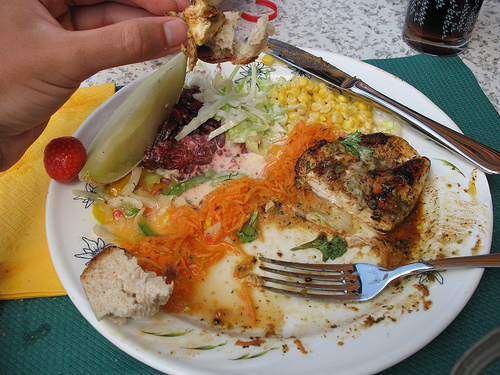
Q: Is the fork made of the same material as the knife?
A: Yes, both the fork and the knife are made of metal.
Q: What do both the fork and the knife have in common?
A: The material, both the fork and the knife are metallic.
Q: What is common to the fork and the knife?
A: The material, both the fork and the knife are metallic.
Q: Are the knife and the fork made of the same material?
A: Yes, both the knife and the fork are made of metal.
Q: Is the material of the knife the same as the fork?
A: Yes, both the knife and the fork are made of metal.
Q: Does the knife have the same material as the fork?
A: Yes, both the knife and the fork are made of metal.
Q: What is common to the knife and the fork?
A: The material, both the knife and the fork are metallic.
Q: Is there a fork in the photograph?
A: Yes, there is a fork.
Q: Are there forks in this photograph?
A: Yes, there is a fork.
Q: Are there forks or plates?
A: Yes, there is a fork.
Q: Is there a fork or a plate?
A: Yes, there is a fork.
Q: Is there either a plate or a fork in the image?
A: Yes, there is a fork.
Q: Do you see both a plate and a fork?
A: Yes, there are both a fork and a plate.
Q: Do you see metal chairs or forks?
A: Yes, there is a metal fork.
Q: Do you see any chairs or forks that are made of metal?
A: Yes, the fork is made of metal.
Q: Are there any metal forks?
A: Yes, there is a metal fork.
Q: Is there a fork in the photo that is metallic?
A: Yes, there is a fork that is metallic.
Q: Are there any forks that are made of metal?
A: Yes, there is a fork that is made of metal.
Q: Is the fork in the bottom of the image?
A: Yes, the fork is in the bottom of the image.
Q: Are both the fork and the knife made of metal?
A: Yes, both the fork and the knife are made of metal.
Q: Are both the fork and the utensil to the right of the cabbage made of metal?
A: Yes, both the fork and the knife are made of metal.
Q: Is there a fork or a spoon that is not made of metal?
A: No, there is a fork but it is made of metal.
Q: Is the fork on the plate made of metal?
A: Yes, the fork is made of metal.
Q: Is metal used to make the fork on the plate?
A: Yes, the fork is made of metal.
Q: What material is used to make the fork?
A: The fork is made of metal.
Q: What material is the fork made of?
A: The fork is made of metal.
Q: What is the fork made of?
A: The fork is made of metal.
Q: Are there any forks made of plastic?
A: No, there is a fork but it is made of metal.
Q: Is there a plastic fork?
A: No, there is a fork but it is made of metal.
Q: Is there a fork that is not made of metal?
A: No, there is a fork but it is made of metal.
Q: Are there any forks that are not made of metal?
A: No, there is a fork but it is made of metal.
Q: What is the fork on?
A: The fork is on the plate.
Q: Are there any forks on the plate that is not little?
A: Yes, there is a fork on the plate.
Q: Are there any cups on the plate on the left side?
A: No, there is a fork on the plate.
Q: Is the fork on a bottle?
A: No, the fork is on the plate.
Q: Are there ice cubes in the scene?
A: No, there are no ice cubes.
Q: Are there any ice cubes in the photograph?
A: No, there are no ice cubes.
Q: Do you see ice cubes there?
A: No, there are no ice cubes.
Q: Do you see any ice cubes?
A: No, there are no ice cubes.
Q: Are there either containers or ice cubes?
A: No, there are no ice cubes or containers.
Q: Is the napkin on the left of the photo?
A: Yes, the napkin is on the left of the image.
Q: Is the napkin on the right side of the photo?
A: No, the napkin is on the left of the image.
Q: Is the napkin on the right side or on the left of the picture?
A: The napkin is on the left of the image.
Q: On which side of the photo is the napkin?
A: The napkin is on the left of the image.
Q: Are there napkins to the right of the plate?
A: No, the napkin is to the left of the plate.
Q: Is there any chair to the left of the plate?
A: No, there is a napkin to the left of the plate.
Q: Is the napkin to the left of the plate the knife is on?
A: Yes, the napkin is to the left of the plate.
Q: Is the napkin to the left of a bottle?
A: No, the napkin is to the left of the plate.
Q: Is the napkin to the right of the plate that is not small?
A: No, the napkin is to the left of the plate.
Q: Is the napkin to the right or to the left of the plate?
A: The napkin is to the left of the plate.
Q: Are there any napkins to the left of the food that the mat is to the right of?
A: Yes, there is a napkin to the left of the food.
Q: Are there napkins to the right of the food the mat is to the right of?
A: No, the napkin is to the left of the food.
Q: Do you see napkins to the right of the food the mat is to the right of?
A: No, the napkin is to the left of the food.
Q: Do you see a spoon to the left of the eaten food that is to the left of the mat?
A: No, there is a napkin to the left of the food.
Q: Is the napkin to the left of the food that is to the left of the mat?
A: Yes, the napkin is to the left of the food.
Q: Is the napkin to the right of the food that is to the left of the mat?
A: No, the napkin is to the left of the food.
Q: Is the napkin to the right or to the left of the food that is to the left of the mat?
A: The napkin is to the left of the food.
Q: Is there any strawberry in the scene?
A: Yes, there is a strawberry.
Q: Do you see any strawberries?
A: Yes, there is a strawberry.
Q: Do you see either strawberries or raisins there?
A: Yes, there is a strawberry.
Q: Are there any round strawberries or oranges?
A: Yes, there is a round strawberry.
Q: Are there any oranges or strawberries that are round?
A: Yes, the strawberry is round.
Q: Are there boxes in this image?
A: No, there are no boxes.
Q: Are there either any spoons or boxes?
A: No, there are no boxes or spoons.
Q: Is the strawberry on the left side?
A: Yes, the strawberry is on the left of the image.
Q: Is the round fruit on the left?
A: Yes, the strawberry is on the left of the image.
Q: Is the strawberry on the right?
A: No, the strawberry is on the left of the image.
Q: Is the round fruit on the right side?
A: No, the strawberry is on the left of the image.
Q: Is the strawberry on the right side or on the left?
A: The strawberry is on the left of the image.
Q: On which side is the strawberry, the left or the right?
A: The strawberry is on the left of the image.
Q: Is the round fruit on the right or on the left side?
A: The strawberry is on the left of the image.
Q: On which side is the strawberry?
A: The strawberry is on the left of the image.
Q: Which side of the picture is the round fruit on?
A: The strawberry is on the left of the image.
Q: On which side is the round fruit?
A: The strawberry is on the left of the image.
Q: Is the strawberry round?
A: Yes, the strawberry is round.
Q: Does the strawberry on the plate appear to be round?
A: Yes, the strawberry is round.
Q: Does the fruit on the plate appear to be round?
A: Yes, the strawberry is round.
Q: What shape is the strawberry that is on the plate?
A: The strawberry is round.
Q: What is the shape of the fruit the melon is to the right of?
A: The strawberry is round.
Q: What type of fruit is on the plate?
A: The fruit is a strawberry.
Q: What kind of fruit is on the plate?
A: The fruit is a strawberry.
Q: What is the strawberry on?
A: The strawberry is on the plate.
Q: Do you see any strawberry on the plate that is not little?
A: Yes, there is a strawberry on the plate.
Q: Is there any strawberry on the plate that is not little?
A: Yes, there is a strawberry on the plate.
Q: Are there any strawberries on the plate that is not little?
A: Yes, there is a strawberry on the plate.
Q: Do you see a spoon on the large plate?
A: No, there is a strawberry on the plate.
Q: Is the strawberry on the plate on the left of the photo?
A: Yes, the strawberry is on the plate.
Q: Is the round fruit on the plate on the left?
A: Yes, the strawberry is on the plate.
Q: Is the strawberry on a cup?
A: No, the strawberry is on the plate.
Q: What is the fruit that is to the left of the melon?
A: The fruit is a strawberry.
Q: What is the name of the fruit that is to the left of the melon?
A: The fruit is a strawberry.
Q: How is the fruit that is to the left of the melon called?
A: The fruit is a strawberry.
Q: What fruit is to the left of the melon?
A: The fruit is a strawberry.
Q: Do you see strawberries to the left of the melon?
A: Yes, there is a strawberry to the left of the melon.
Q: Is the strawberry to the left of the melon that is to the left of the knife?
A: Yes, the strawberry is to the left of the melon.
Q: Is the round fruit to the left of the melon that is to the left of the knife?
A: Yes, the strawberry is to the left of the melon.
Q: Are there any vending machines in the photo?
A: No, there are no vending machines.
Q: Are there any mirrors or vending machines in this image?
A: No, there are no vending machines or mirrors.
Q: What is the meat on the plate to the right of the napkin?
A: The meat is chicken.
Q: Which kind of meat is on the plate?
A: The meat is chicken.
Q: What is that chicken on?
A: The chicken is on the plate.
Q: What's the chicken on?
A: The chicken is on the plate.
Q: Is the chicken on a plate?
A: Yes, the chicken is on a plate.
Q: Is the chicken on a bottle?
A: No, the chicken is on a plate.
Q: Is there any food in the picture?
A: Yes, there is food.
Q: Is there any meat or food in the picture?
A: Yes, there is food.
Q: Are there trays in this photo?
A: No, there are no trays.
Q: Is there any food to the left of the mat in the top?
A: Yes, there is food to the left of the mat.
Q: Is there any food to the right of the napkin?
A: Yes, there is food to the right of the napkin.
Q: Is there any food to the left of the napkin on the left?
A: No, the food is to the right of the napkin.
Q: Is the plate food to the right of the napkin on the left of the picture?
A: Yes, the food is to the right of the napkin.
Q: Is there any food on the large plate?
A: Yes, there is food on the plate.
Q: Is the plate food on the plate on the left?
A: Yes, the food is on the plate.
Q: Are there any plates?
A: Yes, there is a plate.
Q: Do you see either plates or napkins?
A: Yes, there is a plate.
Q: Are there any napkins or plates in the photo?
A: Yes, there is a plate.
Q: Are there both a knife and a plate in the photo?
A: Yes, there are both a plate and a knife.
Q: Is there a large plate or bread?
A: Yes, there is a large plate.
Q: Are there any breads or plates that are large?
A: Yes, the plate is large.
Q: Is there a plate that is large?
A: Yes, there is a large plate.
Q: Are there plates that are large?
A: Yes, there is a plate that is large.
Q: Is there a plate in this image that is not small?
A: Yes, there is a large plate.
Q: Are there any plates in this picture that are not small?
A: Yes, there is a large plate.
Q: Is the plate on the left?
A: Yes, the plate is on the left of the image.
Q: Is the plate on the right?
A: No, the plate is on the left of the image.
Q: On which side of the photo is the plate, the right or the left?
A: The plate is on the left of the image.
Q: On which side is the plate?
A: The plate is on the left of the image.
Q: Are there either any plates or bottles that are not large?
A: No, there is a plate but it is large.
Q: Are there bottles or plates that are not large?
A: No, there is a plate but it is large.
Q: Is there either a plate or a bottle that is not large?
A: No, there is a plate but it is large.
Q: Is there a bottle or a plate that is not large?
A: No, there is a plate but it is large.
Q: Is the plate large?
A: Yes, the plate is large.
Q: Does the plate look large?
A: Yes, the plate is large.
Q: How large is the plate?
A: The plate is large.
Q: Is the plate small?
A: No, the plate is large.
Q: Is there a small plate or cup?
A: No, there is a plate but it is large.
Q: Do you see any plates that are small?
A: No, there is a plate but it is large.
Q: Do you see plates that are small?
A: No, there is a plate but it is large.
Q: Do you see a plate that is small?
A: No, there is a plate but it is large.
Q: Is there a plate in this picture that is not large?
A: No, there is a plate but it is large.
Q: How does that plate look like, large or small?
A: The plate is large.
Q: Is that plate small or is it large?
A: The plate is large.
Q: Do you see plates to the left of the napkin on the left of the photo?
A: No, the plate is to the right of the napkin.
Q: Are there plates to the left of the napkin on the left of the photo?
A: No, the plate is to the right of the napkin.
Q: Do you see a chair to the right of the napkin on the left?
A: No, there is a plate to the right of the napkin.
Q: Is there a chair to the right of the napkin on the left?
A: No, there is a plate to the right of the napkin.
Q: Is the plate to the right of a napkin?
A: Yes, the plate is to the right of a napkin.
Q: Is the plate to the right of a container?
A: No, the plate is to the right of a napkin.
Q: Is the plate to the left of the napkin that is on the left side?
A: No, the plate is to the right of the napkin.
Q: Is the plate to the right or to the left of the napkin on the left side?
A: The plate is to the right of the napkin.